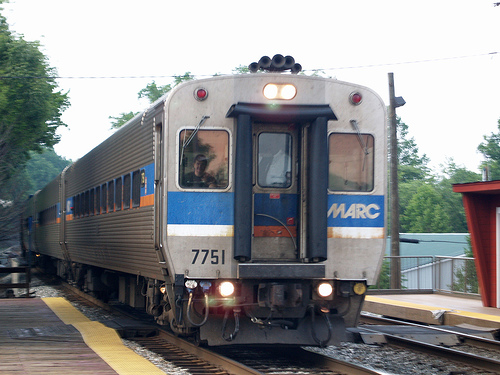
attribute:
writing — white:
[325, 200, 380, 222]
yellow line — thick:
[38, 293, 176, 374]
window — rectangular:
[326, 130, 376, 195]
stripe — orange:
[38, 177, 155, 229]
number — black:
[185, 239, 202, 283]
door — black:
[233, 104, 323, 260]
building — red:
[445, 167, 497, 322]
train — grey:
[21, 73, 411, 362]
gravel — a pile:
[323, 344, 488, 374]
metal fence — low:
[129, 80, 424, 318]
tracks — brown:
[192, 343, 342, 374]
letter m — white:
[321, 200, 347, 221]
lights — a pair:
[259, 78, 299, 102]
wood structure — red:
[442, 176, 499, 311]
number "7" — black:
[200, 246, 210, 265]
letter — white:
[325, 201, 346, 218]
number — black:
[185, 246, 226, 270]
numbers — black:
[187, 245, 226, 265]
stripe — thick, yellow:
[43, 287, 168, 373]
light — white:
[219, 277, 236, 299]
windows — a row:
[36, 169, 145, 225]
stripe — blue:
[165, 192, 385, 237]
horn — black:
[244, 51, 308, 73]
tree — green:
[3, 1, 86, 215]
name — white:
[333, 210, 376, 255]